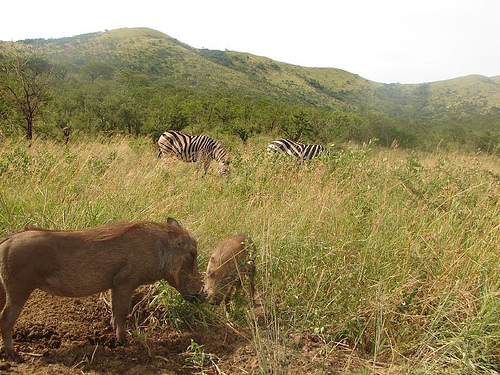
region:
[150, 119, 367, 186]
two zebras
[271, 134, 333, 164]
black and white stripes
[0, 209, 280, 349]
two animals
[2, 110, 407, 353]
four animals standing in the grass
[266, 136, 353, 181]
zebra half hidden by the tall grass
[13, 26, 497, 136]
green hill range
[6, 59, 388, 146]
bright green trees with dark brown tree trunks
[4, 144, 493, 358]
tall green and brown grass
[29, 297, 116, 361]
patch of brown dirt in the grass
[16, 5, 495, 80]
bright, clear sky with no clouds in sight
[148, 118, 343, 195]
two zebras in the grass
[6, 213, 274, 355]
two small brown animals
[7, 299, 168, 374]
small brown patch of dirt amidst the tall grass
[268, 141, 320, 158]
black and white stripes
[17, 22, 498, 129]
green hills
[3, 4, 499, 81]
clear skies with no clouds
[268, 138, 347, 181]
zebra mostly hidden by the tall grass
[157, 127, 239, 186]
zebra putting its head down in the grass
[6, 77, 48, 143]
tree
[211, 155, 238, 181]
the head of a zebra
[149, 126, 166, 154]
the tail of a zebra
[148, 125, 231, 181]
a zebra in the grass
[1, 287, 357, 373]
a patch of brown dirt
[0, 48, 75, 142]
a small green tree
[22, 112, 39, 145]
the trunk of a tree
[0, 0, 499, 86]
a bright gray sky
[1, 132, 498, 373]
a green grassy field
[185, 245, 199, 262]
the eye of an animal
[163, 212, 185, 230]
the ear of an animal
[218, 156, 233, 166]
the ears of a zebra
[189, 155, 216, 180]
the legs of a zebra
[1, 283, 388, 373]
brown dirt on the ground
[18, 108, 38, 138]
a brown tree trunk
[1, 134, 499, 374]
a grassy green field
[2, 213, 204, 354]
adult brown boar pig in tall grass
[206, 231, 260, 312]
baby brown boar pig in tall grass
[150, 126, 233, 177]
black and white zebra grazing in grass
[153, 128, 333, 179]
two black and white zebras grazing in grass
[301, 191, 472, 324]
patch of tall yellow and green grass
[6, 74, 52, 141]
leafless bare brown tree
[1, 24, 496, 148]
grass covered green hills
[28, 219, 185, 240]
brown boar pig mane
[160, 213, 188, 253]
brown boar pig ears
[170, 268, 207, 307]
brown boar pig snout